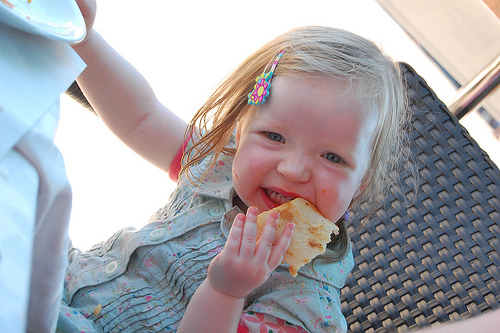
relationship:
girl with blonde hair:
[73, 26, 415, 321] [172, 24, 409, 148]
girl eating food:
[73, 26, 415, 321] [255, 198, 339, 275]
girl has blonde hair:
[73, 26, 415, 321] [172, 24, 409, 148]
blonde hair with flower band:
[172, 24, 409, 148] [244, 50, 280, 109]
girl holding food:
[73, 26, 415, 321] [255, 198, 339, 275]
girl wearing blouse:
[73, 26, 415, 321] [72, 134, 351, 331]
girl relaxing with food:
[73, 26, 415, 321] [255, 198, 339, 275]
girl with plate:
[73, 26, 415, 321] [2, 0, 87, 54]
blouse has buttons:
[72, 134, 351, 331] [82, 200, 227, 278]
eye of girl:
[255, 127, 288, 146] [73, 26, 415, 321]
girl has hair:
[73, 26, 415, 321] [172, 24, 409, 148]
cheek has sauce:
[316, 182, 342, 209] [317, 185, 346, 195]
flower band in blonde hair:
[244, 50, 280, 109] [172, 24, 409, 148]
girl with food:
[73, 26, 415, 321] [255, 198, 339, 275]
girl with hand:
[73, 26, 415, 321] [209, 206, 292, 288]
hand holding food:
[209, 206, 292, 288] [255, 198, 339, 275]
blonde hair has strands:
[172, 24, 409, 148] [167, 36, 276, 165]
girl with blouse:
[73, 26, 415, 321] [72, 134, 351, 331]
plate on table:
[2, 0, 87, 54] [3, 30, 72, 331]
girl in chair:
[73, 26, 415, 321] [341, 61, 497, 328]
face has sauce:
[233, 68, 379, 224] [230, 158, 259, 177]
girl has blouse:
[73, 26, 415, 321] [72, 134, 351, 331]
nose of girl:
[276, 145, 316, 185] [73, 26, 415, 321]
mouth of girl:
[261, 184, 312, 210] [73, 26, 415, 321]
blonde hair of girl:
[172, 24, 409, 148] [73, 26, 415, 321]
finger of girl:
[227, 208, 245, 254] [73, 26, 415, 321]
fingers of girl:
[209, 206, 292, 288] [73, 26, 415, 321]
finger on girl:
[227, 208, 245, 254] [73, 26, 415, 321]